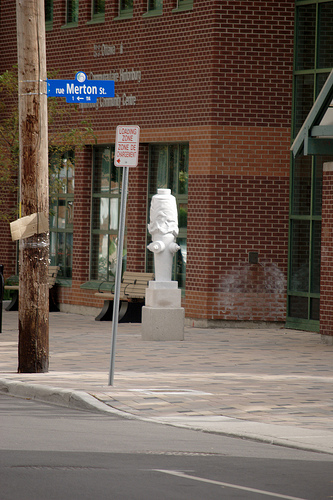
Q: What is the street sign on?
A: Wood pole.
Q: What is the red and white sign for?
A: Loading zones.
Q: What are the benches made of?
A: Wood.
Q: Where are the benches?
A: Near the windows of a building.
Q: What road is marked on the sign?
A: Merton Street.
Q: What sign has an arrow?
A: The road sign.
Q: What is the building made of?
A: Bricks.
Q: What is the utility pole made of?
A: Wood.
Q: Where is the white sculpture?
A: On the sidewalk near the building.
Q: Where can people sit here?
A: On a bench.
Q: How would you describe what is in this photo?
A: A community center building.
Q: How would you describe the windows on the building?
A: Tall and tinted.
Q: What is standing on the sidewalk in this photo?
A: A tall white sculpture.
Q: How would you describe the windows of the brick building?
A: Front windows are tinted.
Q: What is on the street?
A: Manholes.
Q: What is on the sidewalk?
A: Two wooden benches.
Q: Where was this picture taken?
A: On the sidewalk.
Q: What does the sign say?
A: Loading Zone.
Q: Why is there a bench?
A: So people can sit.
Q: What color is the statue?
A: White.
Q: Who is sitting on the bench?
A: No one.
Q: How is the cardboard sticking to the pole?
A: Staples.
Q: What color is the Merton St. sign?
A: Blue.